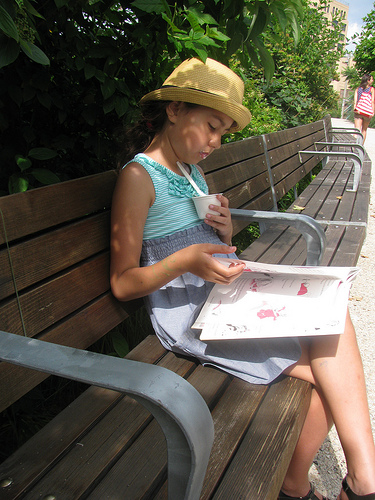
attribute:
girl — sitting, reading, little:
[106, 56, 374, 497]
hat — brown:
[137, 55, 253, 131]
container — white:
[189, 195, 223, 220]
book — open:
[191, 264, 358, 339]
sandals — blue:
[279, 478, 373, 500]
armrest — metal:
[226, 207, 325, 266]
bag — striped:
[355, 91, 374, 117]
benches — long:
[0, 117, 371, 459]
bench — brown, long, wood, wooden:
[0, 168, 313, 499]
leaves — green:
[15, 29, 110, 153]